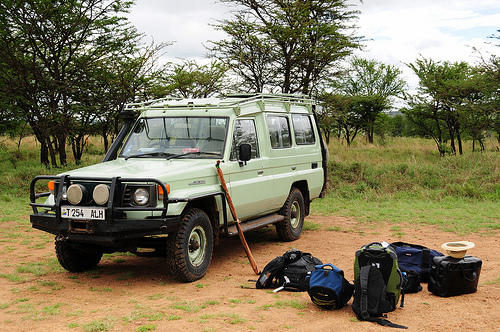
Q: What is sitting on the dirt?
A: Luggage.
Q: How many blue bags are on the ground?
A: 1.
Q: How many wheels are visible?
A: 3.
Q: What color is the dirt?
A: Brown.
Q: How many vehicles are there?
A: 1.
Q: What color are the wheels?
A: Black.